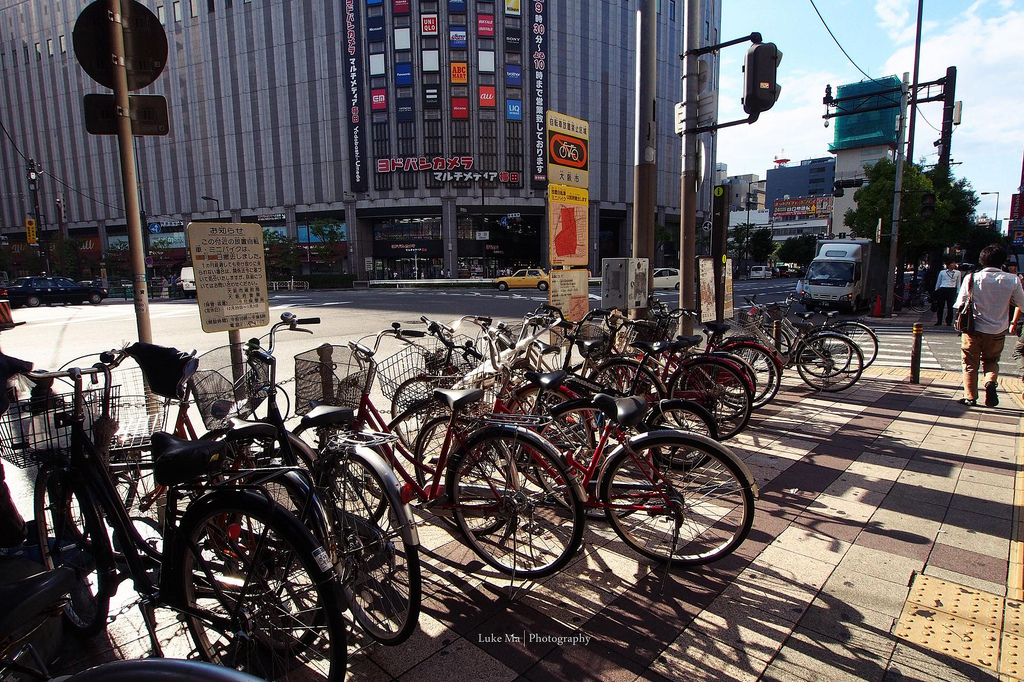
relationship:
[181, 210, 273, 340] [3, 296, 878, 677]
sign near bikes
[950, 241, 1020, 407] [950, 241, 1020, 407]
person with pants